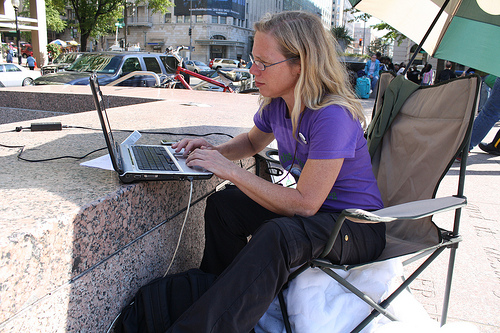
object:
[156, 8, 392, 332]
woman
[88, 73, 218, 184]
laptop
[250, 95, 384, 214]
shirt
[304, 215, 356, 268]
pocket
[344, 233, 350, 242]
silver snap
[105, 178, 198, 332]
cord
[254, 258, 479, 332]
blanket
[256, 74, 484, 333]
chair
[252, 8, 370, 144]
hair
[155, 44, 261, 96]
bicycle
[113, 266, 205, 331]
backpack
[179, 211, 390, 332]
leg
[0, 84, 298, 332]
wall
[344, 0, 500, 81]
umbrella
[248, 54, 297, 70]
glasses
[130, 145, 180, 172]
keyboard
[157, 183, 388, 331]
pants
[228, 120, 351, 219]
arms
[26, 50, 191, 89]
suv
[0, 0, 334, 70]
building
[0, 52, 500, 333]
street